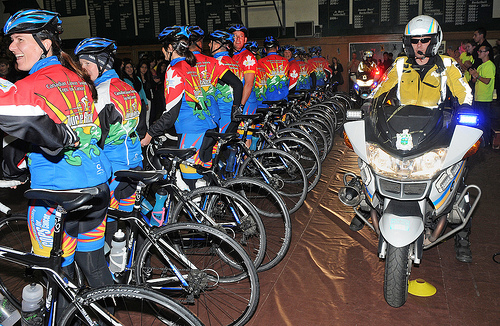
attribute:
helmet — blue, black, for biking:
[0, 8, 72, 40]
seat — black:
[99, 153, 172, 193]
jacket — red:
[367, 53, 472, 108]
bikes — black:
[16, 167, 342, 324]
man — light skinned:
[2, 12, 147, 304]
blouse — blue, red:
[0, 63, 105, 185]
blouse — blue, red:
[92, 68, 144, 164]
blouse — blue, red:
[145, 57, 217, 136]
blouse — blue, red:
[191, 48, 234, 128]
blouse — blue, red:
[217, 53, 241, 133]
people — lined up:
[28, 8, 339, 323]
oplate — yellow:
[408, 270, 440, 297]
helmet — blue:
[393, 26, 430, 48]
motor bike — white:
[335, 107, 482, 307]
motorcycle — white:
[334, 99, 487, 308]